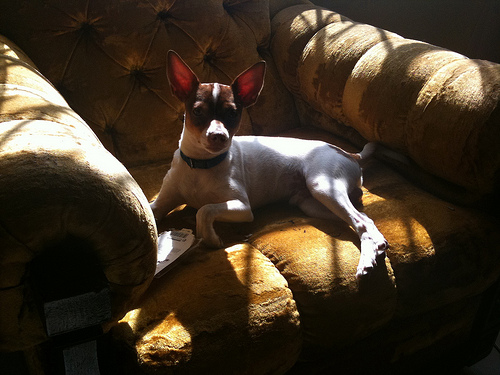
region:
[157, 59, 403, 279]
a white and tan dog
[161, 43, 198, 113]
a right ear of a dog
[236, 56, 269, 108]
a left ear of a dog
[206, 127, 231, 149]
a brown nose of a dog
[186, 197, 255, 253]
the left leg of a dog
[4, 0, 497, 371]
a dog sitting in a chair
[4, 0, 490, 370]
a brown and white dog sitting in a chair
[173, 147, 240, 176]
a blue collar on a dog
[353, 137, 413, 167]
a white tail on a dog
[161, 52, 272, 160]
A brown and white head of a dog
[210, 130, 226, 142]
The nose of the dog.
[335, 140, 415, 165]
The tail of the dog.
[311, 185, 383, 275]
The back legs of the dog.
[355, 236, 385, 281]
The back paws of the dog.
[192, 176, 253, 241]
The front right leg of the dog.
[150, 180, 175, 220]
The front left leg of the dog.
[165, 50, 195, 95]
The left ear of the dog.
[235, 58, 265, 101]
The right ear of the dog.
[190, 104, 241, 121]
The eyes of the dog.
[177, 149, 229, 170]
The collar the dog is wearing.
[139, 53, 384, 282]
Small dog laying on a chair.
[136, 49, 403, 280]
Small dog with a blue collar.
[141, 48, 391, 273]
Small brown and white dog on a chair.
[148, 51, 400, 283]
Small dog with his ears up.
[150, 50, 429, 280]
Small brown and white dog laying down.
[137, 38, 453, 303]
Small dog sitting on an overstuffed chair.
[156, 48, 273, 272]
Brown and white dog with a piece of chewed up paper.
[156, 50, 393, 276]
Small dog with his ears perked up.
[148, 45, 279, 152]
head of a dog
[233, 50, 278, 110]
ear of a dog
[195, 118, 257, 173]
nose of a dog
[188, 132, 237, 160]
mouth of a dog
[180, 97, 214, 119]
eye of a dog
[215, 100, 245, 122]
eye of a dog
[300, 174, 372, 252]
leg of a dog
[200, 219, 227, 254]
paw of a dog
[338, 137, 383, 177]
tail of a dog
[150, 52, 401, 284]
the dog is on the couch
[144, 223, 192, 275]
the dog holds and object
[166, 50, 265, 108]
the dog has pointy ears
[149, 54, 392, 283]
the dog has a white body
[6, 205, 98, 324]
part of the couch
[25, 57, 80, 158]
part of the couch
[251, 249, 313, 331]
part of the couch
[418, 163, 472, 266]
part of the couch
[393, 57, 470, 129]
part of the couch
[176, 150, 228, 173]
black collar on dog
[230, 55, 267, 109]
pointed ear on dog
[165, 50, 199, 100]
pointed ear on dog